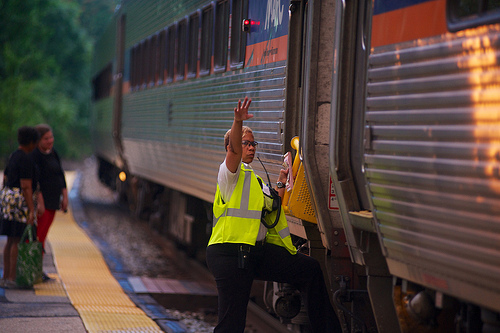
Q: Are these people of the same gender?
A: Yes, all the people are female.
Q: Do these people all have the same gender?
A: Yes, all the people are female.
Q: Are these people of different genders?
A: No, all the people are female.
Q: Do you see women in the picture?
A: Yes, there is a woman.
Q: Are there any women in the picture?
A: Yes, there is a woman.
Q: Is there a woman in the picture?
A: Yes, there is a woman.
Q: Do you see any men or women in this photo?
A: Yes, there is a woman.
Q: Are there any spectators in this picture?
A: No, there are no spectators.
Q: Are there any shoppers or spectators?
A: No, there are no spectators or shoppers.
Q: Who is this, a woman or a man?
A: This is a woman.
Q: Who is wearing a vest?
A: The woman is wearing a vest.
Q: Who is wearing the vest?
A: The woman is wearing a vest.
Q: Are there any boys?
A: No, there are no boys.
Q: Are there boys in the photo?
A: No, there are no boys.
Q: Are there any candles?
A: No, there are no candles.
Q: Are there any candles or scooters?
A: No, there are no candles or scooters.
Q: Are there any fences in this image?
A: No, there are no fences.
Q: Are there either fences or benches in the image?
A: No, there are no fences or benches.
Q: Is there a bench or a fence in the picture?
A: No, there are no fences or benches.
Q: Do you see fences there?
A: No, there are no fences.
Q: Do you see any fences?
A: No, there are no fences.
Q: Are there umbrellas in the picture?
A: No, there are no umbrellas.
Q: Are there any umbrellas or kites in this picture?
A: No, there are no umbrellas or kites.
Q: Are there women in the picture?
A: Yes, there is a woman.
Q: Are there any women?
A: Yes, there is a woman.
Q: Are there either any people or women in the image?
A: Yes, there is a woman.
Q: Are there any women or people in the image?
A: Yes, there is a woman.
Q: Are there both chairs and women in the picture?
A: No, there is a woman but no chairs.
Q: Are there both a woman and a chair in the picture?
A: No, there is a woman but no chairs.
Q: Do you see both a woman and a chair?
A: No, there is a woman but no chairs.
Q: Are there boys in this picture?
A: No, there are no boys.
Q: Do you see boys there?
A: No, there are no boys.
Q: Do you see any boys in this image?
A: No, there are no boys.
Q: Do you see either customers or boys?
A: No, there are no boys or customers.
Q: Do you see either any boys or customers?
A: No, there are no boys or customers.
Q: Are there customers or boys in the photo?
A: No, there are no boys or customers.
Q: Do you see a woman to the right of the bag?
A: Yes, there is a woman to the right of the bag.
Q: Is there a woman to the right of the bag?
A: Yes, there is a woman to the right of the bag.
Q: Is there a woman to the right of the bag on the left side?
A: Yes, there is a woman to the right of the bag.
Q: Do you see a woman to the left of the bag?
A: No, the woman is to the right of the bag.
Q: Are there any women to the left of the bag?
A: No, the woman is to the right of the bag.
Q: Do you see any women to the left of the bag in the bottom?
A: No, the woman is to the right of the bag.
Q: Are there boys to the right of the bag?
A: No, there is a woman to the right of the bag.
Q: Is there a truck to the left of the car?
A: No, there is a woman to the left of the car.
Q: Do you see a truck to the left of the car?
A: No, there is a woman to the left of the car.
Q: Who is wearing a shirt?
A: The woman is wearing a shirt.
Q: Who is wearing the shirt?
A: The woman is wearing a shirt.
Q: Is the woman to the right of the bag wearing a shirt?
A: Yes, the woman is wearing a shirt.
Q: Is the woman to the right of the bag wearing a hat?
A: No, the woman is wearing a shirt.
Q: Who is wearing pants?
A: The woman is wearing pants.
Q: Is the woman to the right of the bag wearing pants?
A: Yes, the woman is wearing pants.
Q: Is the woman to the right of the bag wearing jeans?
A: No, the woman is wearing pants.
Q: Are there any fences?
A: No, there are no fences.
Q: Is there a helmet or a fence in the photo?
A: No, there are no fences or helmets.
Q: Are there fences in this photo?
A: No, there are no fences.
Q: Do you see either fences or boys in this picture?
A: No, there are no fences or boys.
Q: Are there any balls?
A: No, there are no balls.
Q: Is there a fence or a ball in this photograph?
A: No, there are no balls or fences.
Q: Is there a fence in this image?
A: No, there are no fences.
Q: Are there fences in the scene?
A: No, there are no fences.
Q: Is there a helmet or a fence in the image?
A: No, there are no fences or helmets.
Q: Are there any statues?
A: No, there are no statues.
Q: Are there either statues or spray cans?
A: No, there are no statues or spray cans.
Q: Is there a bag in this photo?
A: Yes, there is a bag.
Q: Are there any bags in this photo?
A: Yes, there is a bag.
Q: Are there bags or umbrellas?
A: Yes, there is a bag.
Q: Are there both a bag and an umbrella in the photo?
A: No, there is a bag but no umbrellas.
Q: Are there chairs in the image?
A: No, there are no chairs.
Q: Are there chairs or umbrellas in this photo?
A: No, there are no chairs or umbrellas.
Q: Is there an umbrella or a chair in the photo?
A: No, there are no chairs or umbrellas.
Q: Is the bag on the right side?
A: No, the bag is on the left of the image.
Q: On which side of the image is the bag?
A: The bag is on the left of the image.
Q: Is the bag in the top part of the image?
A: No, the bag is in the bottom of the image.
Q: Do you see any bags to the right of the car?
A: No, the bag is to the left of the car.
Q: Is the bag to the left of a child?
A: No, the bag is to the left of the car.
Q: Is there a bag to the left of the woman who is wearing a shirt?
A: Yes, there is a bag to the left of the woman.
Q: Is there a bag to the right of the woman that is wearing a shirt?
A: No, the bag is to the left of the woman.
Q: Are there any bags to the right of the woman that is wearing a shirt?
A: No, the bag is to the left of the woman.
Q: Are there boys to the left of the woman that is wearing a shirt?
A: No, there is a bag to the left of the woman.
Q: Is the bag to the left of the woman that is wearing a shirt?
A: Yes, the bag is to the left of the woman.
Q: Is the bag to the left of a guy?
A: No, the bag is to the left of the woman.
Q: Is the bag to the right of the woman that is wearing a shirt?
A: No, the bag is to the left of the woman.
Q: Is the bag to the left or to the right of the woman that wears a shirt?
A: The bag is to the left of the woman.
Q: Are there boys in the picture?
A: No, there are no boys.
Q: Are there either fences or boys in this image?
A: No, there are no boys or fences.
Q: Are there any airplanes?
A: No, there are no airplanes.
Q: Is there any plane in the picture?
A: No, there are no airplanes.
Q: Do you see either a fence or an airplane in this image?
A: No, there are no airplanes or fences.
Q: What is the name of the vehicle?
A: The vehicle is a car.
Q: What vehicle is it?
A: The vehicle is a car.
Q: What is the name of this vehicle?
A: This is a car.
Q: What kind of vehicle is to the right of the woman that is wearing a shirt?
A: The vehicle is a car.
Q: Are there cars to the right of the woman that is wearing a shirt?
A: Yes, there is a car to the right of the woman.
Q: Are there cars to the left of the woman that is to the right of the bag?
A: No, the car is to the right of the woman.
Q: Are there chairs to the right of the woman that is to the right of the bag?
A: No, there is a car to the right of the woman.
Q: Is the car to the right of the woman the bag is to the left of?
A: Yes, the car is to the right of the woman.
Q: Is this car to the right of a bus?
A: No, the car is to the right of the woman.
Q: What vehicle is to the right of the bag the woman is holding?
A: The vehicle is a car.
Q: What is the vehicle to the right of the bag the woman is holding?
A: The vehicle is a car.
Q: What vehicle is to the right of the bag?
A: The vehicle is a car.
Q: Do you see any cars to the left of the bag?
A: No, the car is to the right of the bag.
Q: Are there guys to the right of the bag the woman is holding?
A: No, there is a car to the right of the bag.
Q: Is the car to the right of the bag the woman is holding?
A: Yes, the car is to the right of the bag.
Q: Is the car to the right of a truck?
A: No, the car is to the right of the bag.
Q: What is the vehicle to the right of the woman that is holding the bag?
A: The vehicle is a car.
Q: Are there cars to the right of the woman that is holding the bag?
A: Yes, there is a car to the right of the woman.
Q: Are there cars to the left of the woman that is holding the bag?
A: No, the car is to the right of the woman.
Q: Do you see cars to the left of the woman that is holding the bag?
A: No, the car is to the right of the woman.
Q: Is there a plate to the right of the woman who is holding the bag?
A: No, there is a car to the right of the woman.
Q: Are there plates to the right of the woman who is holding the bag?
A: No, there is a car to the right of the woman.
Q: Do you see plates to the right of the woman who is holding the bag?
A: No, there is a car to the right of the woman.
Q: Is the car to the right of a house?
A: No, the car is to the right of the woman.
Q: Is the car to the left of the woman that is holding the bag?
A: No, the car is to the right of the woman.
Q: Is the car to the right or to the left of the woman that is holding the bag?
A: The car is to the right of the woman.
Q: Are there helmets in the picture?
A: No, there are no helmets.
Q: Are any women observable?
A: Yes, there is a woman.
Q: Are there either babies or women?
A: Yes, there is a woman.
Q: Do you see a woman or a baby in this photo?
A: Yes, there is a woman.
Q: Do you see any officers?
A: No, there are no officers.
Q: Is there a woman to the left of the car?
A: Yes, there is a woman to the left of the car.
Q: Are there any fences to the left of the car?
A: No, there is a woman to the left of the car.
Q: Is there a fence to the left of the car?
A: No, there is a woman to the left of the car.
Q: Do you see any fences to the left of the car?
A: No, there is a woman to the left of the car.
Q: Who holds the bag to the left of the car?
A: The woman holds the bag.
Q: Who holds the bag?
A: The woman holds the bag.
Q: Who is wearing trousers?
A: The woman is wearing trousers.